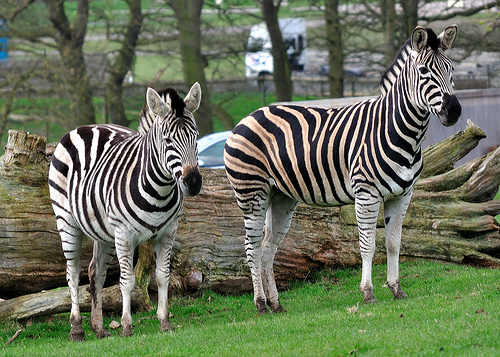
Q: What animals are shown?
A: Zebra.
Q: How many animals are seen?
A: Two.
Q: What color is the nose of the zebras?
A: Black.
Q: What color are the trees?
A: Brown.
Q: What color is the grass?
A: Green.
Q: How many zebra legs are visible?
A: Eight.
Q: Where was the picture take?
A: In a zoo.